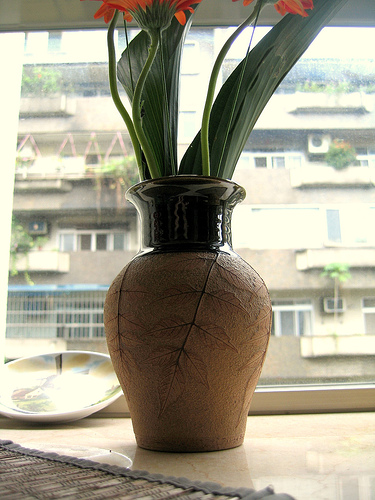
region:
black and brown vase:
[108, 173, 268, 453]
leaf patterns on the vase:
[114, 263, 246, 416]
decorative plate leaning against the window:
[5, 352, 122, 422]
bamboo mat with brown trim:
[3, 443, 293, 499]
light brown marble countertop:
[11, 418, 372, 496]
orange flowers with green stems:
[96, 0, 332, 178]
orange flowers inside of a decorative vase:
[96, 1, 301, 450]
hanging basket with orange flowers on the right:
[326, 140, 356, 171]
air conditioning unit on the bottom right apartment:
[323, 296, 347, 313]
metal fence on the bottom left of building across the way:
[9, 292, 109, 337]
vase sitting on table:
[107, 180, 265, 448]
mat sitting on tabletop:
[0, 434, 290, 497]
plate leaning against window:
[6, 339, 106, 420]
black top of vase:
[133, 173, 233, 242]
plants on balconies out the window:
[21, 58, 369, 325]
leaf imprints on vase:
[101, 250, 257, 415]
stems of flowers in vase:
[95, 7, 251, 164]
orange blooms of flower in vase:
[92, 3, 311, 26]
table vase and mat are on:
[5, 411, 370, 496]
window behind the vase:
[1, 22, 363, 379]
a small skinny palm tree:
[321, 263, 353, 336]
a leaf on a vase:
[155, 361, 187, 421]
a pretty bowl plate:
[1, 347, 123, 427]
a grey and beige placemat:
[1, 434, 292, 499]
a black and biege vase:
[102, 172, 272, 454]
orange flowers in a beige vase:
[85, 0, 320, 451]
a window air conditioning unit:
[323, 295, 346, 313]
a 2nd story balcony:
[4, 213, 72, 276]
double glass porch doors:
[75, 229, 112, 251]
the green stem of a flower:
[131, 29, 166, 176]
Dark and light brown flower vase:
[72, 166, 283, 455]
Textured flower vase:
[94, 168, 282, 458]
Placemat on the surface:
[3, 434, 189, 497]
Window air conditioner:
[308, 285, 362, 313]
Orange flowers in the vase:
[82, 1, 358, 279]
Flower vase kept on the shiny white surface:
[80, 160, 301, 473]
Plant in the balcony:
[321, 139, 369, 182]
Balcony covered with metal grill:
[8, 281, 108, 343]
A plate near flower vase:
[7, 337, 121, 430]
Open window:
[7, 9, 373, 392]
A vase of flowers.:
[93, 0, 346, 451]